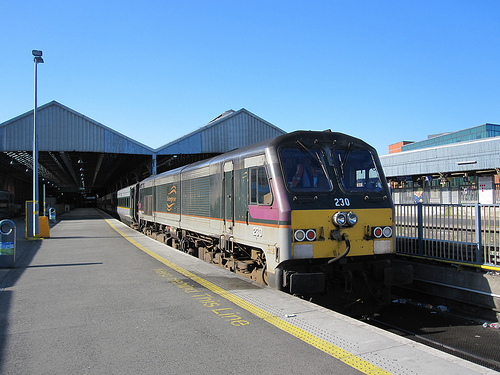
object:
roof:
[140, 130, 303, 183]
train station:
[0, 96, 500, 375]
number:
[345, 198, 351, 207]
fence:
[394, 202, 499, 271]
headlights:
[295, 230, 305, 241]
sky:
[0, 0, 500, 146]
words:
[210, 307, 250, 328]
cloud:
[121, 106, 182, 134]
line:
[101, 214, 383, 374]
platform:
[0, 216, 500, 375]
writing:
[190, 292, 220, 308]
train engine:
[132, 126, 404, 290]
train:
[109, 128, 401, 293]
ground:
[0, 211, 500, 375]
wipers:
[336, 140, 356, 181]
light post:
[30, 61, 40, 236]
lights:
[373, 227, 383, 238]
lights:
[305, 229, 317, 242]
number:
[334, 198, 341, 207]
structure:
[378, 121, 500, 218]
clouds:
[0, 0, 499, 149]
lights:
[332, 212, 346, 226]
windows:
[276, 133, 336, 195]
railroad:
[319, 275, 500, 372]